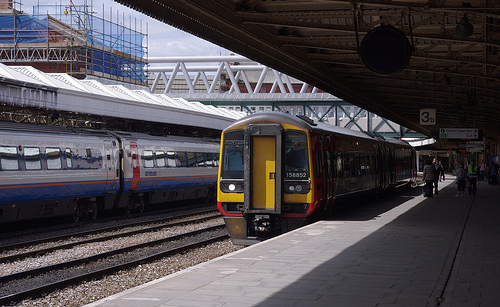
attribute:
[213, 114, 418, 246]
train — parked, yellow, metro, passenger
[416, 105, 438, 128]
sign — hanging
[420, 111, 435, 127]
3b — black, 3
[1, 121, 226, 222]
train — silver, blue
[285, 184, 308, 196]
headlights — round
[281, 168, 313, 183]
number — white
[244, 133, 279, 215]
door — yellow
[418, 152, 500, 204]
people — waiting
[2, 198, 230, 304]
tracks — black, unattended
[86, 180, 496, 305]
platform — grey, stone, concrete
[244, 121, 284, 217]
frame — black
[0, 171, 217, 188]
strip — red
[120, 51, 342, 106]
pipe — white, grey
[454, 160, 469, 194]
person — walking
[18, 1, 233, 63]
cloud — grey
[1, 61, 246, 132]
roof — white